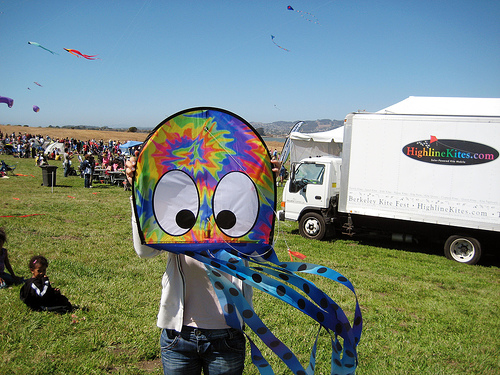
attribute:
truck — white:
[294, 107, 499, 257]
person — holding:
[117, 194, 284, 372]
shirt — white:
[130, 192, 252, 329]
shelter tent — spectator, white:
[289, 127, 344, 170]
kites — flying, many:
[0, 2, 297, 120]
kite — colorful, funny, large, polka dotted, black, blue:
[134, 89, 373, 374]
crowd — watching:
[1, 130, 136, 194]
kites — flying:
[1, 5, 324, 117]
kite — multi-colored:
[137, 130, 261, 247]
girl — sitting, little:
[9, 247, 86, 312]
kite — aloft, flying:
[27, 39, 60, 57]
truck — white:
[267, 90, 499, 254]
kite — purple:
[25, 88, 396, 337]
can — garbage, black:
[42, 170, 62, 190]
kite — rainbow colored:
[126, 109, 270, 256]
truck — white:
[265, 95, 483, 282]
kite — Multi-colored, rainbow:
[128, 106, 363, 373]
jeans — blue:
[146, 321, 252, 373]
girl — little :
[18, 252, 74, 313]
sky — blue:
[8, 11, 486, 119]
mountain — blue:
[253, 18, 429, 99]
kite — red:
[65, 48, 100, 67]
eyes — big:
[154, 166, 261, 237]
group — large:
[14, 130, 126, 178]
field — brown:
[18, 120, 139, 139]